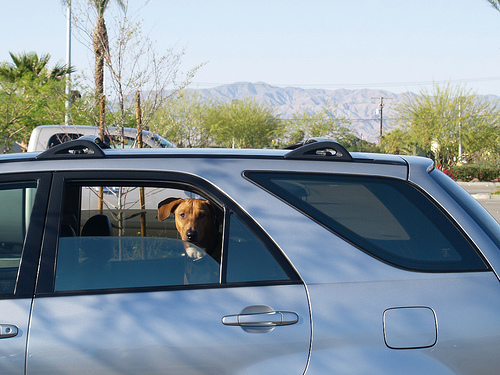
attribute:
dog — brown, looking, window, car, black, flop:
[167, 192, 227, 260]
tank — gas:
[384, 304, 435, 350]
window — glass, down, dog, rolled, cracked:
[101, 230, 186, 266]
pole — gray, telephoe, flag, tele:
[61, 11, 81, 139]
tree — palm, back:
[81, 36, 118, 118]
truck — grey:
[50, 104, 158, 161]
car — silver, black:
[6, 105, 368, 318]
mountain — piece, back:
[232, 46, 409, 142]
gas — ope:
[366, 296, 450, 375]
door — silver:
[9, 244, 308, 373]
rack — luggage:
[276, 106, 377, 173]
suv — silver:
[67, 109, 180, 152]